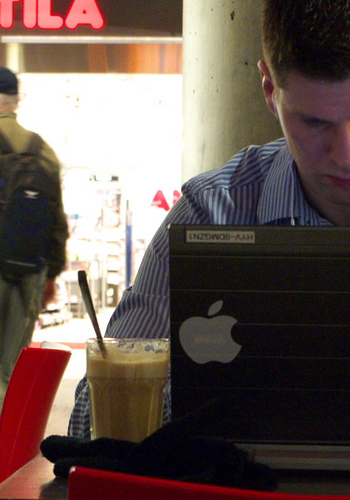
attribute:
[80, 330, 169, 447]
glass — filled, clear, tall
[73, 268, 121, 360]
spoon — plastic, black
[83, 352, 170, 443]
substance — beige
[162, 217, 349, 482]
laptop — apple, black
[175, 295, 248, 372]
apple logo — white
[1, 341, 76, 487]
chair — red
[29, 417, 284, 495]
gloves — black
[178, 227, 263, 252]
label — white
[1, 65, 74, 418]
person — old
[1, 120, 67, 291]
backpack — black, large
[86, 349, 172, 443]
coffee — mixed, yellow, brown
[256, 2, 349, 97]
hair — short, brown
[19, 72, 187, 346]
entrance — lit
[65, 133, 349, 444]
shirt — long sleeve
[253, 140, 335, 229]
collar — blue, white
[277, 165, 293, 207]
stripes — vertical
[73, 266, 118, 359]
handle — silverware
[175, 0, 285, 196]
pole — large, white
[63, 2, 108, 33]
letter — red, capital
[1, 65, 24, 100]
cap — black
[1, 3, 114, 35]
letters — red